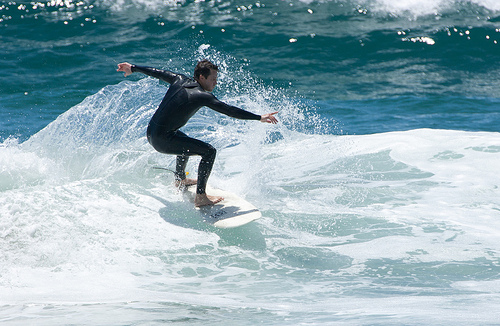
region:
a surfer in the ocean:
[109, 40, 285, 250]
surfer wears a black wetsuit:
[108, 49, 288, 216]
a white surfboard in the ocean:
[149, 162, 270, 237]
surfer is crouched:
[103, 43, 293, 219]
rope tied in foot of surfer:
[146, 162, 196, 212]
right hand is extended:
[186, 54, 287, 130]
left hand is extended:
[103, 42, 195, 94]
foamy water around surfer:
[8, 125, 498, 321]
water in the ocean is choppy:
[7, 2, 498, 319]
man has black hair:
[164, 43, 244, 114]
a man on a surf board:
[116, 47, 286, 228]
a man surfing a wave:
[115, 57, 282, 227]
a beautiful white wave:
[3, 61, 499, 268]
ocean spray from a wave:
[127, 44, 319, 149]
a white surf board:
[171, 169, 263, 230]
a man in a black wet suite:
[115, 56, 284, 204]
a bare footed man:
[111, 48, 281, 207]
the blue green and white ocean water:
[2, 0, 494, 325]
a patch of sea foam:
[29, 204, 201, 301]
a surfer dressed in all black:
[115, 54, 286, 204]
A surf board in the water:
[210, 205, 258, 217]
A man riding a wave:
[112, 43, 280, 228]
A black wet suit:
[173, 82, 190, 114]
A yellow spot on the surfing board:
[185, 170, 190, 175]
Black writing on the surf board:
[209, 209, 228, 218]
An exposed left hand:
[114, 60, 131, 77]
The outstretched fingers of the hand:
[260, 110, 280, 125]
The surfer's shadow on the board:
[206, 205, 221, 210]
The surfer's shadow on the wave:
[169, 203, 186, 220]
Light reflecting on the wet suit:
[190, 88, 198, 94]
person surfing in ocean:
[94, 40, 302, 212]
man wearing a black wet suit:
[109, 47, 279, 233]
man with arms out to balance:
[97, 40, 294, 241]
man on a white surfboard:
[125, 55, 285, 219]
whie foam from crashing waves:
[353, 178, 461, 260]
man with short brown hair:
[192, 53, 225, 100]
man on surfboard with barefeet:
[158, 164, 225, 223]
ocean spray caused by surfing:
[75, 78, 319, 160]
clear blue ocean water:
[327, 60, 472, 110]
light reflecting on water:
[393, 27, 468, 47]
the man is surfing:
[106, 33, 271, 273]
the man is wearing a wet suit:
[114, 31, 231, 223]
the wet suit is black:
[136, 65, 223, 195]